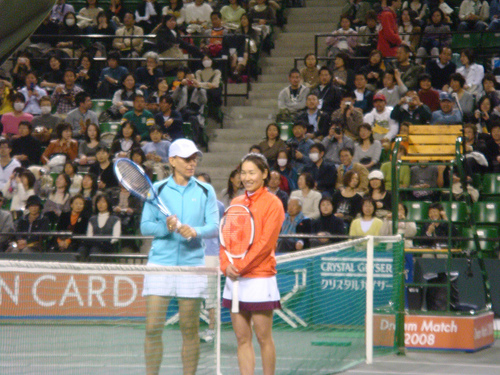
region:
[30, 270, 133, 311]
card written on the wall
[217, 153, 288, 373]
woman wearing orange sweater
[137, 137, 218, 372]
woman wearing blue sweater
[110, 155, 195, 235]
blue tennis racquet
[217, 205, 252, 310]
red tennis racquet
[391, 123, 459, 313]
tall green and tan chair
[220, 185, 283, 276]
the thin orange jacket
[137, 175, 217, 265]
the thing blue jacket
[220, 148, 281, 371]
the woman wearing the the thin orange jacket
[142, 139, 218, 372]
the woman wearing the the thin blue jacket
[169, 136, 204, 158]
the white baseball hat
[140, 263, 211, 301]
the white tennis skirt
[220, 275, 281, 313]
the white and maroon tennis skirt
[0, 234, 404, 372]
the green and white tennis net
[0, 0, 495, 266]
the people in the audience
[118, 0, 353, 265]
the gray concrete stairs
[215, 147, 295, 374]
shorter woman beside net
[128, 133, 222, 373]
taller woman beside net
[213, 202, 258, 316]
woman in orange holding racket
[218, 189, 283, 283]
woman wearing orange jacket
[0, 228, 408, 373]
net separating two women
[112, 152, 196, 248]
woman in blue holding racket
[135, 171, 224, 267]
woman wearing blue jacket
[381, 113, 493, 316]
judges chair at end of net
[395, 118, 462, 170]
judge's seat is wooden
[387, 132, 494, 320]
judge's ladder is green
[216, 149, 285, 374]
female Asian tennis player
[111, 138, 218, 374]
tennis player standing on the court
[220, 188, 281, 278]
orange top of tennis player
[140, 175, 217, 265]
light blue top of tennis player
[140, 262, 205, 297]
white shorts of tennis player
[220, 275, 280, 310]
white skirt with purple trim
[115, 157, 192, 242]
blue and white tennis racket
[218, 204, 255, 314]
purple and white tennis racket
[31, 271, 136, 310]
the word CARD written in white on a sign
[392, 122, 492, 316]
yellow and green high chair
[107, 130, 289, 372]
female tennis players on opposite sides of net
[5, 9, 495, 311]
rows of elevated spectators behind players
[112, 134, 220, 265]
player holding racket at an angle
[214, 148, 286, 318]
player with upright racket in front of body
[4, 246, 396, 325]
orange and blue advertisements over partition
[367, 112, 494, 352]
empty umpire seat on platform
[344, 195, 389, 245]
woman seated close to net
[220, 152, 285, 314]
player wearing orange jacket with striped skirt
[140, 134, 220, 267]
player in white cap and blue jacket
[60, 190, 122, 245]
two women seated in front of railing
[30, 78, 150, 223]
audience in the stands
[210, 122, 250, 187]
the steps are concrete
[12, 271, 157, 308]
the sign is orange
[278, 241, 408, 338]
the net is white